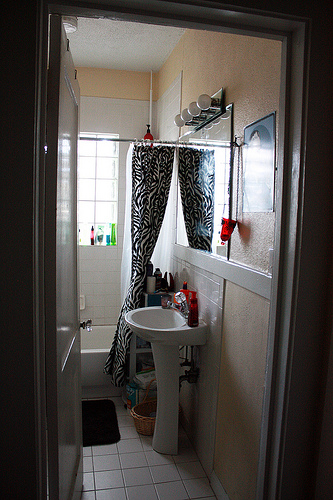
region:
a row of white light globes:
[174, 90, 212, 124]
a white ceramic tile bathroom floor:
[84, 395, 213, 498]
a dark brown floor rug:
[80, 398, 120, 446]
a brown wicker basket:
[132, 376, 182, 439]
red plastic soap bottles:
[176, 280, 198, 328]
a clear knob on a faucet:
[175, 291, 184, 302]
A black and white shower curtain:
[100, 139, 178, 391]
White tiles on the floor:
[78, 392, 218, 497]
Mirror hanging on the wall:
[174, 102, 235, 261]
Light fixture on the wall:
[171, 84, 226, 142]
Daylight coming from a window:
[74, 128, 121, 248]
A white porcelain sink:
[120, 301, 211, 459]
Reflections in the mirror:
[175, 114, 231, 259]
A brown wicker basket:
[129, 396, 186, 439]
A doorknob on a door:
[72, 313, 96, 335]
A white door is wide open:
[42, 11, 96, 498]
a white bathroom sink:
[128, 290, 206, 423]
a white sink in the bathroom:
[111, 274, 201, 387]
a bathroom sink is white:
[122, 287, 269, 426]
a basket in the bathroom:
[123, 382, 199, 445]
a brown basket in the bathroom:
[113, 370, 226, 445]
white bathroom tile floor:
[83, 430, 196, 494]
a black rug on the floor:
[91, 381, 170, 488]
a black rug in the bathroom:
[102, 379, 175, 480]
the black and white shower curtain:
[103, 145, 173, 388]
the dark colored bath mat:
[81, 398, 120, 447]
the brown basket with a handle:
[130, 377, 159, 435]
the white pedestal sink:
[125, 293, 213, 454]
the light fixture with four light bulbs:
[173, 86, 222, 135]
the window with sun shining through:
[78, 132, 119, 245]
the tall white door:
[47, 14, 92, 498]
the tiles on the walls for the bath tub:
[78, 70, 180, 398]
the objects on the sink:
[124, 278, 209, 454]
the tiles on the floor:
[76, 394, 218, 499]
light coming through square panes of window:
[78, 129, 119, 246]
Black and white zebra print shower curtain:
[103, 137, 179, 389]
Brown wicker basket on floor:
[130, 397, 183, 436]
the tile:
[104, 472, 137, 498]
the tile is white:
[117, 468, 154, 490]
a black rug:
[85, 407, 109, 443]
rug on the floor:
[88, 409, 117, 436]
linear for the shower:
[154, 252, 166, 270]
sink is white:
[137, 305, 171, 327]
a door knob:
[82, 320, 97, 333]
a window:
[86, 182, 115, 222]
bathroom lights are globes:
[170, 85, 227, 126]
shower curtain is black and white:
[105, 137, 178, 390]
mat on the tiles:
[81, 394, 125, 450]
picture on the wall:
[240, 108, 276, 218]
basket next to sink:
[130, 377, 180, 439]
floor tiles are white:
[92, 450, 168, 489]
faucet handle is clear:
[174, 291, 186, 304]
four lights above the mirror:
[170, 93, 224, 126]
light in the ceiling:
[58, 14, 81, 36]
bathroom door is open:
[34, 7, 115, 498]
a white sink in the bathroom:
[112, 284, 243, 441]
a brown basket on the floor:
[124, 391, 162, 436]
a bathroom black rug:
[85, 388, 168, 469]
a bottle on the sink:
[183, 281, 201, 317]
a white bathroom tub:
[77, 317, 135, 377]